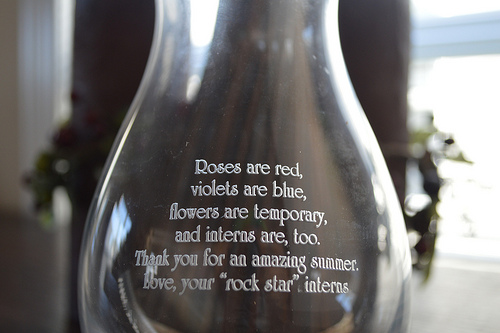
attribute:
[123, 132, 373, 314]
writing — white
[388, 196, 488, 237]
sill — white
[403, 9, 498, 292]
frame — white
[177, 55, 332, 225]
vase — glass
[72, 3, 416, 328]
vase — clear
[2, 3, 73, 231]
blinds — closed